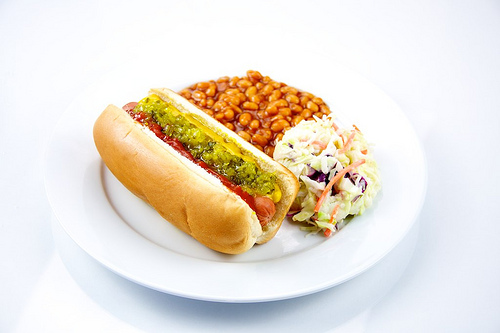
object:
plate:
[58, 61, 429, 304]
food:
[93, 70, 377, 257]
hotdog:
[118, 100, 275, 231]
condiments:
[138, 94, 283, 197]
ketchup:
[134, 112, 255, 207]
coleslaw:
[273, 112, 376, 236]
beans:
[180, 69, 331, 155]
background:
[1, 1, 500, 330]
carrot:
[307, 155, 366, 212]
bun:
[94, 85, 301, 256]